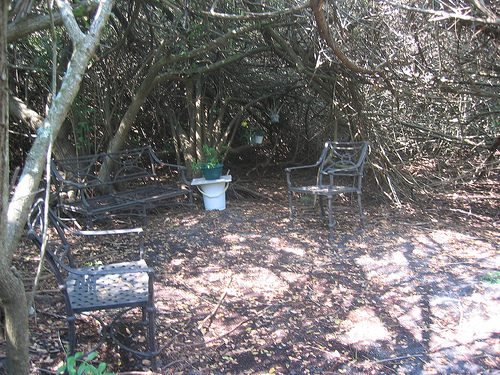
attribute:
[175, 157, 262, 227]
bucket — white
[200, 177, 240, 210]
bucket — white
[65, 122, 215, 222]
bench — grey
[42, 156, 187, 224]
bench — black, iron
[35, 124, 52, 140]
leaf — green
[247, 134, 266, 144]
bucket — white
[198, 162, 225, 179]
bucket — white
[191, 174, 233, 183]
board — white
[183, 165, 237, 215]
table — white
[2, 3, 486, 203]
trees — dead-looking